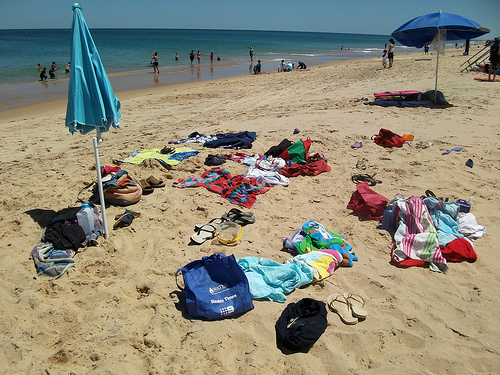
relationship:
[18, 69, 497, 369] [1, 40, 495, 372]
beach has sand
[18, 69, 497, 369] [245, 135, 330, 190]
beach has belongings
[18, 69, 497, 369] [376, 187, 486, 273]
beach has belongings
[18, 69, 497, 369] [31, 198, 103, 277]
beach has belongings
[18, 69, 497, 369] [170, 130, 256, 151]
beach has belongings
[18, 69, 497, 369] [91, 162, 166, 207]
beach has belongings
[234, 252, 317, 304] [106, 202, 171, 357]
clothes are on ground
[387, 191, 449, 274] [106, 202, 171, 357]
towel are on ground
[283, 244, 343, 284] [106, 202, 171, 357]
clothes are on ground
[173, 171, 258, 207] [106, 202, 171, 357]
clothes are on ground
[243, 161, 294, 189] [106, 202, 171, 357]
clothes are on ground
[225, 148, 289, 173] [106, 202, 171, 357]
clothes are on ground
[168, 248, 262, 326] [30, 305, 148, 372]
bag on sand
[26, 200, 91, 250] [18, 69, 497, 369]
belonging on beach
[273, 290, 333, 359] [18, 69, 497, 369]
belonging on beach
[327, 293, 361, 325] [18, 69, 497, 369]
shoes on beach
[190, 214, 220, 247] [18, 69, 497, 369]
belonging on beach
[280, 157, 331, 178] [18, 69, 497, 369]
belonging on beach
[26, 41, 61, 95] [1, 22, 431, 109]
people playing in ocean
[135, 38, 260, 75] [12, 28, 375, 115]
people walking by ocean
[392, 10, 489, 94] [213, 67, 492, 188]
umbrella on beach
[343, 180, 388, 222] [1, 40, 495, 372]
bag on sand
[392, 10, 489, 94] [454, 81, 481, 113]
umbrella on beach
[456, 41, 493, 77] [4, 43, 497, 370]
stairs on beach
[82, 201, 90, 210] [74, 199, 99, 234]
cap on water jug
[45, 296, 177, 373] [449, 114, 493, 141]
sand on ground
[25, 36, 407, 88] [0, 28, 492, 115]
people in ocean